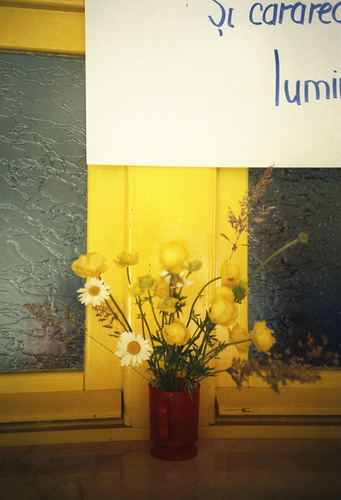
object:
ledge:
[0, 421, 341, 445]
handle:
[158, 398, 169, 443]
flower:
[117, 329, 152, 371]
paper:
[84, 0, 340, 167]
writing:
[207, 1, 340, 109]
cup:
[145, 373, 202, 462]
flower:
[157, 323, 189, 349]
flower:
[201, 295, 241, 330]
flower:
[253, 322, 279, 350]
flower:
[159, 243, 190, 271]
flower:
[69, 253, 108, 279]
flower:
[23, 168, 341, 465]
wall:
[0, 0, 341, 444]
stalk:
[100, 277, 134, 333]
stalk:
[184, 276, 219, 326]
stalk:
[181, 317, 210, 354]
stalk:
[147, 290, 165, 342]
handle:
[209, 390, 295, 433]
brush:
[23, 163, 339, 388]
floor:
[0, 437, 340, 499]